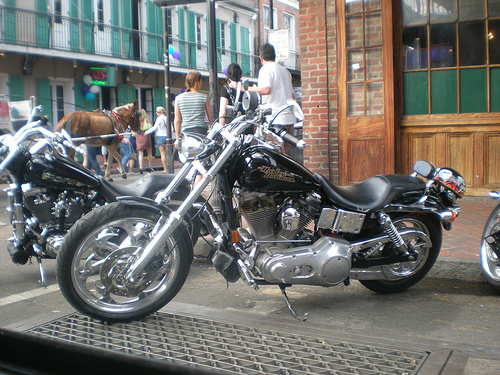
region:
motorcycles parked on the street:
[6, 83, 481, 364]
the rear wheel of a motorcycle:
[354, 203, 444, 299]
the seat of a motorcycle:
[313, 162, 423, 217]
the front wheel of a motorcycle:
[59, 192, 207, 327]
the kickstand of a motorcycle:
[276, 286, 317, 325]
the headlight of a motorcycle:
[173, 129, 220, 161]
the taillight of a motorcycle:
[436, 206, 457, 227]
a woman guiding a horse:
[48, 93, 170, 186]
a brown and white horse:
[56, 101, 138, 182]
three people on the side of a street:
[161, 35, 311, 191]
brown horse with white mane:
[60, 97, 148, 175]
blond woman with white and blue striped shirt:
[173, 62, 218, 132]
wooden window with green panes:
[404, 26, 496, 113]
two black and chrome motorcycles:
[6, 111, 464, 331]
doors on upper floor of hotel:
[21, 0, 254, 47]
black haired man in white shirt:
[253, 37, 301, 107]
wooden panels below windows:
[401, 95, 499, 165]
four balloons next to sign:
[63, 63, 118, 102]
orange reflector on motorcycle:
[209, 216, 262, 256]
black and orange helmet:
[412, 150, 482, 212]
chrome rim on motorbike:
[96, 210, 153, 300]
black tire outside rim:
[58, 235, 98, 340]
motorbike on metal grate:
[163, 314, 224, 368]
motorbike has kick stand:
[260, 273, 295, 321]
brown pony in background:
[78, 115, 148, 150]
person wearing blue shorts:
[149, 113, 166, 157]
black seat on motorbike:
[318, 175, 400, 207]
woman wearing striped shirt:
[178, 98, 198, 129]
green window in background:
[433, 101, 450, 111]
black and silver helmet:
[406, 153, 480, 225]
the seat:
[344, 176, 381, 203]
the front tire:
[57, 225, 84, 255]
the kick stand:
[278, 292, 313, 317]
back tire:
[424, 223, 442, 246]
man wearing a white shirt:
[262, 67, 284, 94]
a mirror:
[290, 98, 309, 118]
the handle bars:
[273, 123, 307, 146]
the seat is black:
[340, 178, 381, 199]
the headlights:
[177, 135, 201, 160]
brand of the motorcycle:
[247, 155, 298, 187]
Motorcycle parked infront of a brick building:
[1, 1, 498, 373]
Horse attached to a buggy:
[0, 93, 156, 178]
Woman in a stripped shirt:
[171, 66, 218, 147]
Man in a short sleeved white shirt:
[253, 39, 300, 141]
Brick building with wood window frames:
[299, 0, 499, 215]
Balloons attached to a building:
[79, 68, 111, 105]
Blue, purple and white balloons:
[163, 43, 183, 68]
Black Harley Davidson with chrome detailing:
[56, 79, 471, 328]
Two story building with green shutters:
[1, 0, 261, 155]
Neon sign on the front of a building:
[83, 62, 110, 87]